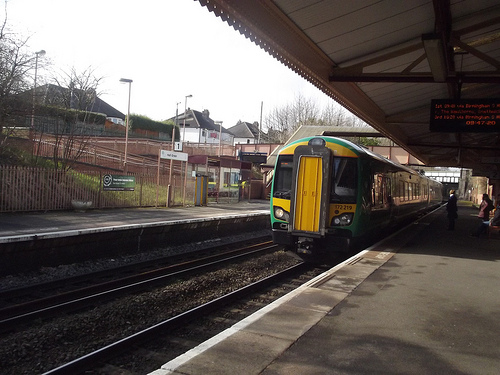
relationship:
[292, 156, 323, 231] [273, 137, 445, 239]
door on train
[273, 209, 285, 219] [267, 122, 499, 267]
light on train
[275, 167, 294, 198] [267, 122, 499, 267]
window on train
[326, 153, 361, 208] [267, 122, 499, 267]
right window on train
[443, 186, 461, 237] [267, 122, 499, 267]
man standing by train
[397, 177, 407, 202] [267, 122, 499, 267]
window on train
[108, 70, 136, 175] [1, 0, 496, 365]
light pole outside station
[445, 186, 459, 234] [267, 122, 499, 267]
person waiting by train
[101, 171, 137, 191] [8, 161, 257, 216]
banner on fence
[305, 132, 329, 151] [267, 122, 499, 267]
light on top of train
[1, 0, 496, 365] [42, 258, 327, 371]
station has tracks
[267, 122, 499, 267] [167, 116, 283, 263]
train at station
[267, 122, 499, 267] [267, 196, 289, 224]
train has light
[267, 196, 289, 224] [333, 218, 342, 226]
light has headlight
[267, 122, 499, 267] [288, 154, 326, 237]
train has door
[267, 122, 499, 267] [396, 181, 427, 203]
train has windows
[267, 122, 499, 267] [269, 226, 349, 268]
train has bumper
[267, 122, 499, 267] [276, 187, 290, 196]
train has wiper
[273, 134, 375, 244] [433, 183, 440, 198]
train has window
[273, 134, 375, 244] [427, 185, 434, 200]
train has window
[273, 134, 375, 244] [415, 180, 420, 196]
train has window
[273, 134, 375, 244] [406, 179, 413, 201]
train has window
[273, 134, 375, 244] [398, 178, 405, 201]
train has window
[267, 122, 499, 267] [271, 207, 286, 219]
train has headlight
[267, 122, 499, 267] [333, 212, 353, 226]
train has headlight